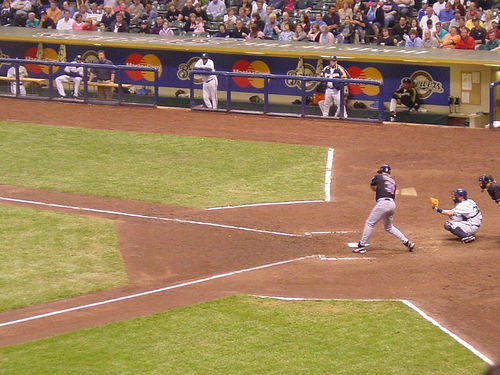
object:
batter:
[363, 161, 409, 247]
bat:
[398, 187, 418, 197]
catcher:
[430, 186, 483, 243]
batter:
[363, 160, 414, 250]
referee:
[472, 181, 484, 190]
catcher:
[427, 182, 480, 238]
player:
[321, 58, 345, 118]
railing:
[258, 75, 381, 119]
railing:
[225, 67, 294, 108]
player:
[320, 58, 350, 121]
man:
[90, 54, 117, 94]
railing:
[114, 61, 162, 100]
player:
[396, 80, 416, 111]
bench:
[429, 99, 448, 119]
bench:
[424, 104, 459, 115]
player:
[386, 73, 418, 118]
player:
[49, 49, 88, 96]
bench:
[49, 79, 130, 97]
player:
[350, 163, 415, 253]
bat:
[392, 187, 421, 202]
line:
[2, 195, 300, 236]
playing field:
[2, 97, 482, 373]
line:
[1, 254, 319, 327]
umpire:
[476, 170, 484, 183]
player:
[383, 76, 422, 125]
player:
[312, 54, 351, 119]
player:
[190, 52, 220, 111]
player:
[50, 55, 87, 102]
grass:
[0, 121, 333, 208]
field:
[131, 200, 484, 314]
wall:
[2, 45, 456, 105]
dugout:
[0, 38, 484, 128]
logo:
[122, 49, 164, 81]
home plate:
[342, 239, 373, 248]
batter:
[351, 159, 420, 257]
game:
[22, 69, 480, 375]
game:
[14, 124, 489, 375]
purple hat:
[448, 185, 469, 200]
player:
[440, 213, 470, 293]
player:
[316, 50, 344, 103]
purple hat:
[326, 121, 338, 136]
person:
[332, 155, 422, 286]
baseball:
[336, 146, 412, 267]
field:
[35, 205, 495, 350]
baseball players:
[18, 79, 434, 109]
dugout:
[12, 99, 494, 172]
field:
[33, 114, 494, 346]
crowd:
[10, 51, 490, 147]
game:
[32, 141, 493, 375]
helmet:
[452, 186, 468, 199]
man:
[424, 177, 485, 281]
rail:
[124, 113, 256, 126]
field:
[14, 156, 498, 263]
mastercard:
[107, 53, 164, 80]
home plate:
[328, 231, 374, 275]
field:
[2, 174, 487, 375]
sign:
[235, 61, 270, 87]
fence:
[0, 54, 385, 123]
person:
[437, 24, 469, 43]